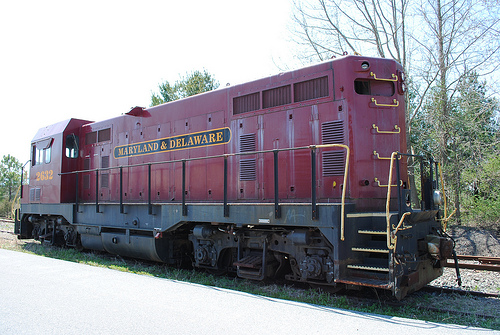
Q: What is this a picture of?
A: Train.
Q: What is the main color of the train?
A: Red.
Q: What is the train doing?
A: Parked.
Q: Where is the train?
A: Train tracks.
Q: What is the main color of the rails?
A: Black.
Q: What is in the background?
A: Trees.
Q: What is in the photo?
A: Train.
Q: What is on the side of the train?
A: Maryland & delaware.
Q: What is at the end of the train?
A: Steps.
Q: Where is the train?
A: On tracks.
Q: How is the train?
A: Red.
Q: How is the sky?
A: Blue.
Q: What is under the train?
A: Gravel.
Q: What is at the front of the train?
A: Engine.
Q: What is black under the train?
A: Undercarriage.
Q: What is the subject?
A: A train.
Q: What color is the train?
A: Red.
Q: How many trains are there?
A: One.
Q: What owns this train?
A: Maryland & Delaware.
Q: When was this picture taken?
A: Daytime.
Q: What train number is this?
A: 2632.